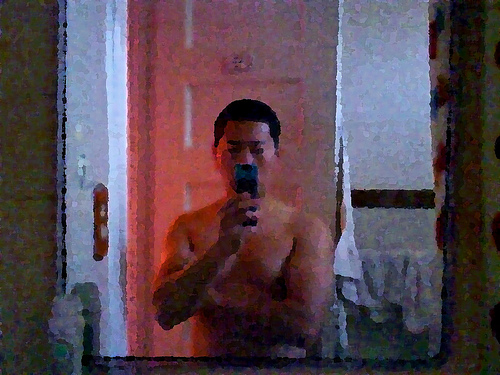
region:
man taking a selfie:
[152, 95, 335, 355]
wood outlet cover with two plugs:
[89, 181, 111, 263]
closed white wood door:
[122, 2, 344, 374]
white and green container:
[43, 289, 86, 374]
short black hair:
[211, 95, 283, 150]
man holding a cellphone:
[152, 97, 337, 356]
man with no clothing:
[150, 94, 334, 361]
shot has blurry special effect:
[1, 0, 498, 373]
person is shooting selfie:
[148, 95, 333, 361]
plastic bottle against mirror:
[48, 294, 85, 374]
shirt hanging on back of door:
[333, 118, 364, 360]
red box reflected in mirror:
[88, 185, 112, 260]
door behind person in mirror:
[129, 2, 346, 362]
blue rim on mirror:
[53, 2, 458, 373]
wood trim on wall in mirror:
[343, 186, 438, 211]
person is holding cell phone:
[231, 161, 261, 227]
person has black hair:
[211, 98, 284, 166]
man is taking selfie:
[175, 83, 325, 296]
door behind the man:
[105, 9, 385, 359]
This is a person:
[132, 87, 360, 374]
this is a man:
[114, 92, 385, 347]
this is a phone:
[218, 162, 276, 250]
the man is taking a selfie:
[150, 109, 362, 346]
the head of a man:
[197, 91, 304, 226]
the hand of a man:
[232, 222, 343, 350]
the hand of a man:
[118, 205, 275, 343]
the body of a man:
[177, 191, 289, 365]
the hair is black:
[207, 96, 289, 150]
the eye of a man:
[251, 138, 273, 162]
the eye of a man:
[217, 136, 241, 164]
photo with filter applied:
[5, 5, 497, 374]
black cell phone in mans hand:
[233, 170, 258, 218]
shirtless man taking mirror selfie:
[157, 95, 337, 365]